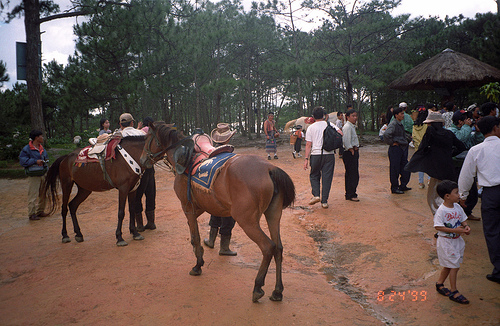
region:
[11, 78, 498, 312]
a crowd of people and horses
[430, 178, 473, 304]
a kid wearing white shorts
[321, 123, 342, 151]
a black backpack the is using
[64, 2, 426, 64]
a green treeline in the background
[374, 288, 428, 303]
print of the date the photo was taken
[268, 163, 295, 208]
a wagging tail of the horse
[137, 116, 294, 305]
a brown horse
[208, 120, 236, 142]
a hat the guy is wearing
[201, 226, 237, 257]
pair of boots the person is wearing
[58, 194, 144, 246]
four legs of the horse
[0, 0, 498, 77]
cloud cover in sky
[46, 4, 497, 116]
needles of pine trees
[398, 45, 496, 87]
thatched roof with point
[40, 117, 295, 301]
two standing brown horses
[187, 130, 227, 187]
red saddle on blue blanket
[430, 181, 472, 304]
child walking in sandals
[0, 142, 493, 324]
ground made of red clay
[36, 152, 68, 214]
tail on back of horse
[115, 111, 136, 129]
cap on man's head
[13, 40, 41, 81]
back of sign on tree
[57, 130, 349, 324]
Two horses standing.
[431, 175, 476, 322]
A little boy by the man.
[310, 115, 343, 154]
The person is carrying a back pack.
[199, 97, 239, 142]
The man is wearing a hat.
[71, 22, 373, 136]
Tall trees in the background.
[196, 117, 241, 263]
A man standing by the horse.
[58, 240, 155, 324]
The ground is red clay.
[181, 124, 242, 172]
The horse has a saddle.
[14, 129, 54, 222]
A man standing by the horse tail.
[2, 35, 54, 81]
A sign hanging on the tree.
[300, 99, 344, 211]
person standing near horses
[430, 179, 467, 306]
person standing near horses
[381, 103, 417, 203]
person standing near horses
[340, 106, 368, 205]
person standing near horses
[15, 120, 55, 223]
person standing near horses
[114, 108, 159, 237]
person standing near horses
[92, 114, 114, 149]
person standing near horses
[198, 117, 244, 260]
person standing near horses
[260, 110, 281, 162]
person standing near horses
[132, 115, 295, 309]
horse in a group of people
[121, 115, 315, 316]
Horse standing on red dirt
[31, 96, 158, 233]
Horse standing on red dirt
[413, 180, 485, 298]
Little boy wearing white clothes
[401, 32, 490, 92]
Straw hut in background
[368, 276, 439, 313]
Date of picture taken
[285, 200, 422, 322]
Small stream of water flowing through dirt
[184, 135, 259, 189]
Blue and yellow rug on horse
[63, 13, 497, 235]
Tall green trees in background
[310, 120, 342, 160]
Black backpack on man in white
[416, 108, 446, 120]
Tan hat on person wearing cape